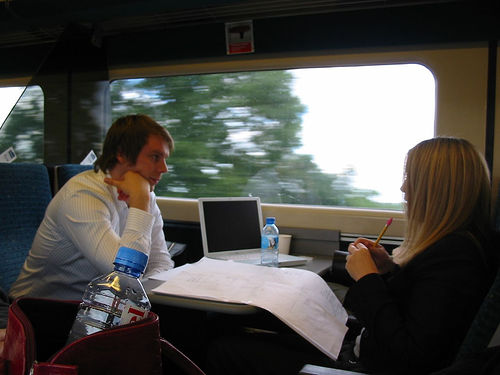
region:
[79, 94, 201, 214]
This is a person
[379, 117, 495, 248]
This is a person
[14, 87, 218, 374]
This is a person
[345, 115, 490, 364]
This is a person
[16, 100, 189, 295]
Person is sitting down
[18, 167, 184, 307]
Shirt is white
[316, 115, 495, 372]
Girl is wearing black shirt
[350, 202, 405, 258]
Holding a pencil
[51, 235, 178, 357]
Bottle is full of water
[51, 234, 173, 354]
Clear bottle with a blue top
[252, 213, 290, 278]
A bottle on the table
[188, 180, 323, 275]
This is a laptop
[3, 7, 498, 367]
They are on a train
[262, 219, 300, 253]
this is a paper cup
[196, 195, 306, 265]
A laptop on a table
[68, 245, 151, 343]
A bottle of water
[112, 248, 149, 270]
A blue cap on the bottle of water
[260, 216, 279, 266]
A bottle of water near the laptop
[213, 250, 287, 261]
The keyboard on the laptop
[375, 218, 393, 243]
A pencil in the woman's right hand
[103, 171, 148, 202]
The right hand of the man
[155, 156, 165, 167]
The nose of the man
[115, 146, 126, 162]
The right ear of the man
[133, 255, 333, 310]
A table between the people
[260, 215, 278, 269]
Bottle of water between the people.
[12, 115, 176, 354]
A man in a white striped shirt sitting at a table.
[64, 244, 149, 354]
Clear bottle of water with a blue lid sticking out of a purse.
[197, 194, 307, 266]
a silver and black laptop that is off.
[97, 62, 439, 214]
A large window beside these two people.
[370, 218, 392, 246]
A yellow pencil in a woman's hand with a pink eraser.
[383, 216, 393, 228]
Pink eraser on the end of a pencil.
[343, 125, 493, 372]
A blonde woman in black holding a pencil.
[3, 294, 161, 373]
A red purse with a bottle of water inside it.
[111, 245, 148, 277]
The closest blue lid on a clear water bottle.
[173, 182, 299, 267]
laptop on the table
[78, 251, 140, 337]
bottle in the bag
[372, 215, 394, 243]
pencil in woman's hand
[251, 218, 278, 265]
bottle of water on table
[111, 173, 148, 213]
hand of the man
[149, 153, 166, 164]
eye of the man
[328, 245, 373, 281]
hand of the woman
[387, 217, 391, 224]
eraser on the pencil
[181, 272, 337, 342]
paper on the table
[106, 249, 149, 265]
top on the water